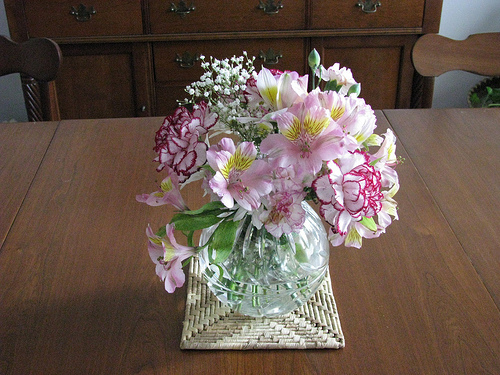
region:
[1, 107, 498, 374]
A brown dining room table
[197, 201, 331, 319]
A glass vase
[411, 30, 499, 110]
A wood chair top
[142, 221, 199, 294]
A pink flower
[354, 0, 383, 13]
A bronze drawer pull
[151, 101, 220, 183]
A white and purple flower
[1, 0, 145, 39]
A brown drawer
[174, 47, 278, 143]
White baby's breath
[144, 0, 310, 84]
Two brown drawers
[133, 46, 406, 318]
Flowers in a glass vase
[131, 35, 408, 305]
a bouquet of flower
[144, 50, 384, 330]
flowers in a short vase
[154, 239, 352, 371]
a white mat under vase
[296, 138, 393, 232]
white flower with red tips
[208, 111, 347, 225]
pink flowers with some yellow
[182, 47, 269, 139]
little white baby's breath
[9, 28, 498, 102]
the tops to two wood chairs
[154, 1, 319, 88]
several handles on a piece of furniture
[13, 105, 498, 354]
a solid wood table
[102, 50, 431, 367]
a vase of flowers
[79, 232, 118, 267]
part of a board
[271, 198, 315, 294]
part of a flower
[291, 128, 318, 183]
part of a flower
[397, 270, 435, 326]
part of a table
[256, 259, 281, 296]
part of a vase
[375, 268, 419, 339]
part of a table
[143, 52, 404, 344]
assortment of flowers in crystal vase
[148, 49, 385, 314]
flower arrangement in crystal vase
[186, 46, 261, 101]
baby's breath flowers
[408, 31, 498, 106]
back of wooden chair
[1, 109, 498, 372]
large wooden dining table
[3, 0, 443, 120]
lower part of a wooden hutch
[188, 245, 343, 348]
woven straw protective mat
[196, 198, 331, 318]
round crystal flower vase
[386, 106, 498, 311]
leaf of wooden table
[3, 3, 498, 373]
bouquet of flowers in crystal vase on wooden dining table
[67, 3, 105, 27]
a handle on the drawer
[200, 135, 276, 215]
a pink and yellow flower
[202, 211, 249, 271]
a green leaf of the flower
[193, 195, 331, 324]
a clear vase on the table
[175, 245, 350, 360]
a brown place mat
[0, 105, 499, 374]
a brown wooden table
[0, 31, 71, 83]
the back of a chair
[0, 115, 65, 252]
a crack in the table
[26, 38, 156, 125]
a brown wooden cabinet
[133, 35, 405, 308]
a floral arrangement in the vase